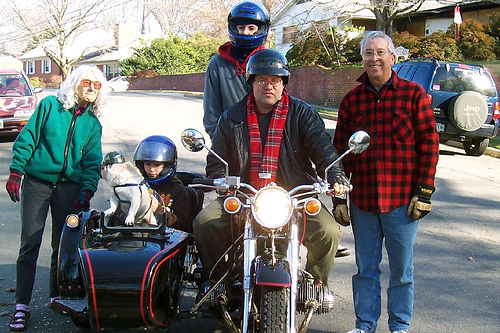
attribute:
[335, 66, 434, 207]
shirt — red and black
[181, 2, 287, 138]
person — young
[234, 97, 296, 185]
redscarf — red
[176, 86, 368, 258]
jacket — black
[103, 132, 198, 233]
person — young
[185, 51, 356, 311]
man — plaid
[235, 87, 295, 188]
scarf — red, blue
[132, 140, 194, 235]
person — young